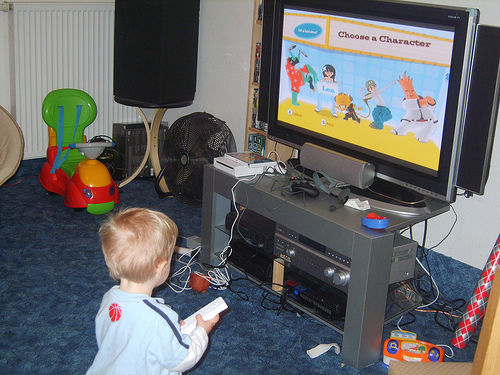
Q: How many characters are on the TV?
A: 5.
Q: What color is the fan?
A: Black.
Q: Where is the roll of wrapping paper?
A: Against the wall.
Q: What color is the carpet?
A: Blue.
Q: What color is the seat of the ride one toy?
A: Green.